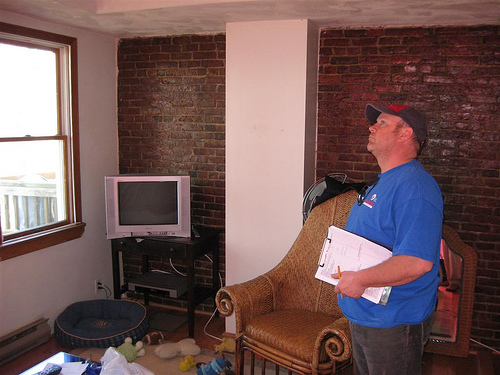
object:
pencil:
[337, 265, 343, 300]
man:
[331, 103, 444, 375]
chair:
[214, 190, 361, 375]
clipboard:
[314, 224, 392, 306]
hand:
[331, 271, 366, 299]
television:
[104, 175, 191, 240]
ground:
[446, 357, 489, 370]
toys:
[144, 330, 164, 345]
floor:
[1, 297, 252, 374]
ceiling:
[0, 1, 499, 28]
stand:
[111, 225, 222, 338]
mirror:
[428, 235, 463, 344]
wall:
[433, 27, 499, 240]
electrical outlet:
[94, 280, 103, 294]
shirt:
[337, 159, 444, 328]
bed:
[53, 297, 151, 349]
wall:
[117, 26, 500, 347]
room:
[2, 0, 490, 367]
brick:
[118, 25, 500, 349]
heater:
[0, 317, 53, 368]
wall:
[2, 12, 114, 352]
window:
[0, 20, 86, 261]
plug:
[97, 282, 102, 289]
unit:
[128, 270, 197, 299]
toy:
[115, 337, 145, 362]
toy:
[154, 338, 201, 358]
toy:
[214, 337, 236, 354]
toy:
[179, 355, 196, 371]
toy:
[197, 357, 232, 374]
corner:
[109, 61, 139, 171]